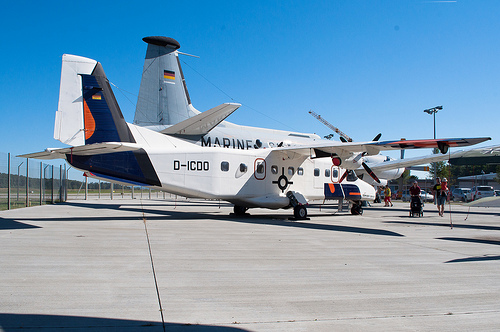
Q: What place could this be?
A: It is an airport.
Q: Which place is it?
A: It is an airport.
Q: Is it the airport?
A: Yes, it is the airport.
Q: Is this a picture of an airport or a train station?
A: It is showing an airport.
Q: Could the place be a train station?
A: No, it is an airport.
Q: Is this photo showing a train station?
A: No, the picture is showing an airport.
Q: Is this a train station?
A: No, it is an airport.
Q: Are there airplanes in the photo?
A: Yes, there is an airplane.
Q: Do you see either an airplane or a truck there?
A: Yes, there is an airplane.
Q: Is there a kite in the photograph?
A: No, there are no kites.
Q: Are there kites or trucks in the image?
A: No, there are no kites or trucks.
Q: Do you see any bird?
A: No, there are no birds.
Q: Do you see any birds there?
A: No, there are no birds.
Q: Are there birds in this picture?
A: No, there are no birds.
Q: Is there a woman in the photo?
A: Yes, there is a woman.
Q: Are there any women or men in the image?
A: Yes, there is a woman.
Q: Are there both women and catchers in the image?
A: No, there is a woman but no catchers.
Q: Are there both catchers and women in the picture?
A: No, there is a woman but no catchers.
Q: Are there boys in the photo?
A: No, there are no boys.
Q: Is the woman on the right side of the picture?
A: Yes, the woman is on the right of the image.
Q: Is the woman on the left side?
A: No, the woman is on the right of the image.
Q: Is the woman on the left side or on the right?
A: The woman is on the right of the image.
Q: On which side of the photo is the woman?
A: The woman is on the right of the image.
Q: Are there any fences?
A: Yes, there is a fence.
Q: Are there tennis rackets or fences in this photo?
A: Yes, there is a fence.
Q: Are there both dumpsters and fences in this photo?
A: No, there is a fence but no dumpsters.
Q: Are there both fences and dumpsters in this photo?
A: No, there is a fence but no dumpsters.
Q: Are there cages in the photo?
A: No, there are no cages.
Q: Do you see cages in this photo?
A: No, there are no cages.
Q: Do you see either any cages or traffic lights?
A: No, there are no cages or traffic lights.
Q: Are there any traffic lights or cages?
A: No, there are no cages or traffic lights.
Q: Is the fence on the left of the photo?
A: Yes, the fence is on the left of the image.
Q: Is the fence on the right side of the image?
A: No, the fence is on the left of the image.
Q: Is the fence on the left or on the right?
A: The fence is on the left of the image.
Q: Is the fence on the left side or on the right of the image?
A: The fence is on the left of the image.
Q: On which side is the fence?
A: The fence is on the left of the image.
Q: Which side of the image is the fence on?
A: The fence is on the left of the image.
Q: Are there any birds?
A: No, there are no birds.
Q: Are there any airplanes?
A: Yes, there is an airplane.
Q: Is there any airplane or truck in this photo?
A: Yes, there is an airplane.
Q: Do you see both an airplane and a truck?
A: No, there is an airplane but no trucks.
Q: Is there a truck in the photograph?
A: No, there are no trucks.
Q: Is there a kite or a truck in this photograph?
A: No, there are no trucks or kites.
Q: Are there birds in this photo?
A: No, there are no birds.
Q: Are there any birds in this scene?
A: No, there are no birds.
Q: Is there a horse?
A: No, there are no horses.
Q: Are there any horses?
A: No, there are no horses.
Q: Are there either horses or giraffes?
A: No, there are no horses or giraffes.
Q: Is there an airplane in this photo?
A: Yes, there is an airplane.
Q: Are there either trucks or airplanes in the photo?
A: Yes, there is an airplane.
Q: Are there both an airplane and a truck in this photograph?
A: No, there is an airplane but no trucks.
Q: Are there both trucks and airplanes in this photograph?
A: No, there is an airplane but no trucks.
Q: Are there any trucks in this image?
A: No, there are no trucks.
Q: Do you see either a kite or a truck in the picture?
A: No, there are no trucks or kites.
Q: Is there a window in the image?
A: Yes, there are windows.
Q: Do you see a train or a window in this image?
A: Yes, there are windows.